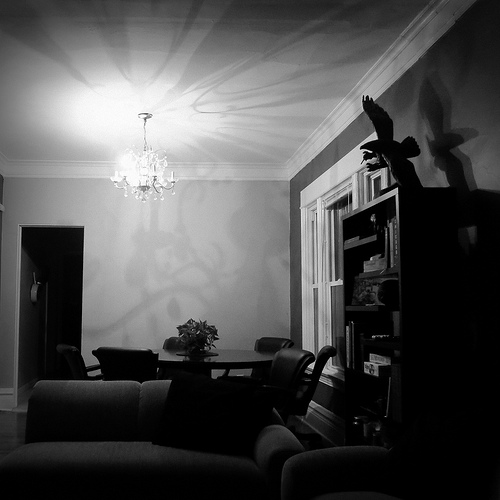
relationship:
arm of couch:
[255, 421, 303, 463] [55, 371, 273, 489]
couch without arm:
[55, 371, 273, 489] [255, 421, 303, 463]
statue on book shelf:
[355, 93, 419, 186] [330, 199, 435, 407]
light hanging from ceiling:
[118, 123, 173, 202] [62, 30, 281, 75]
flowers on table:
[169, 322, 218, 350] [195, 351, 250, 372]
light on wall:
[118, 123, 173, 202] [239, 193, 278, 220]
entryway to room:
[16, 212, 85, 235] [26, 230, 90, 347]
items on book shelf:
[328, 249, 386, 311] [330, 199, 435, 407]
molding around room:
[221, 167, 269, 190] [26, 230, 90, 347]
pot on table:
[184, 347, 206, 357] [195, 351, 250, 372]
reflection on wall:
[68, 2, 241, 84] [239, 193, 278, 220]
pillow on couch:
[168, 379, 254, 456] [55, 371, 273, 489]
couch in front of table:
[55, 371, 273, 489] [195, 351, 250, 372]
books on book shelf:
[328, 178, 381, 202] [330, 199, 435, 407]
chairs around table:
[97, 344, 303, 397] [195, 351, 250, 372]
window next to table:
[271, 177, 346, 335] [195, 351, 250, 372]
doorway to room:
[10, 258, 126, 297] [26, 230, 90, 347]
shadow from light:
[117, 238, 205, 303] [118, 123, 173, 202]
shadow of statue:
[117, 238, 205, 303] [355, 93, 419, 186]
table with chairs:
[195, 351, 250, 372] [97, 344, 303, 397]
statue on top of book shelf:
[355, 93, 419, 186] [330, 199, 435, 407]